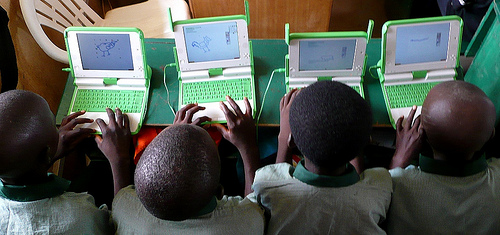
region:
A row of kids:
[7, 77, 492, 211]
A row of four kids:
[6, 80, 491, 230]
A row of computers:
[56, 9, 475, 78]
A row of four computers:
[52, 17, 468, 77]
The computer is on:
[62, 25, 149, 97]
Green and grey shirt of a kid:
[2, 178, 108, 233]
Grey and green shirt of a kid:
[261, 163, 389, 234]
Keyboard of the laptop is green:
[389, 85, 416, 105]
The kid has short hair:
[291, 82, 367, 162]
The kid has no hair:
[418, 83, 499, 179]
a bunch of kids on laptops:
[5, 7, 472, 223]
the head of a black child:
[421, 85, 488, 160]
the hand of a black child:
[387, 113, 438, 154]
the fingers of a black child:
[390, 100, 430, 126]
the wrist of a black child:
[390, 150, 415, 167]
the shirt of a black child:
[395, 168, 497, 232]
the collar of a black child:
[290, 161, 358, 194]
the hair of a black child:
[285, 92, 372, 162]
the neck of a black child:
[300, 150, 355, 185]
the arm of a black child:
[92, 155, 137, 186]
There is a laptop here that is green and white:
[191, 22, 206, 87]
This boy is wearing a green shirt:
[318, 173, 324, 200]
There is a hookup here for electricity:
[161, 60, 171, 110]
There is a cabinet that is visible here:
[258, 7, 268, 40]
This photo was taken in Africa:
[109, 21, 194, 233]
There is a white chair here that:
[31, 13, 43, 48]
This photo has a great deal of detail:
[136, 40, 237, 223]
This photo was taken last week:
[125, 20, 194, 228]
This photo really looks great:
[113, 33, 173, 172]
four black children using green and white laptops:
[0, 17, 496, 219]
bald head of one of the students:
[413, 81, 498, 173]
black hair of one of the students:
[288, 87, 373, 169]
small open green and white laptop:
[50, 24, 154, 137]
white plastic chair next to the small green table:
[17, 2, 192, 55]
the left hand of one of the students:
[389, 109, 423, 167]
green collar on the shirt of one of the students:
[286, 162, 367, 191]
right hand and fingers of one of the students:
[209, 91, 260, 143]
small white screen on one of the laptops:
[174, 24, 249, 68]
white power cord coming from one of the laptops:
[158, 60, 180, 120]